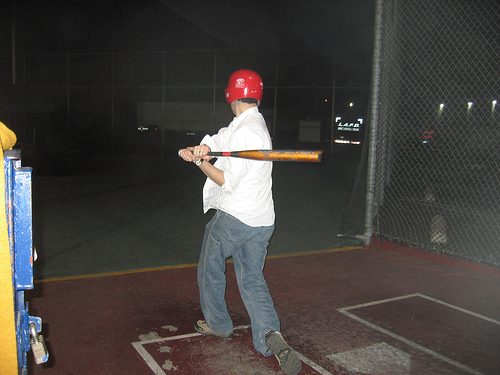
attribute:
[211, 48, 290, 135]
helmet — red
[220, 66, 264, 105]
hat — red